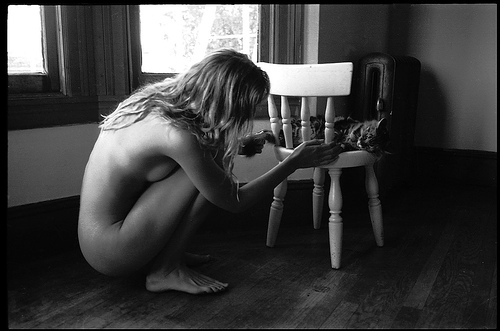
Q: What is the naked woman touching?
A: The chair.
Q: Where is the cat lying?
A: In chair.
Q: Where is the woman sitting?
A: Next to floor.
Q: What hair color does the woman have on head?
A: Blonde.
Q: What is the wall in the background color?
A: White.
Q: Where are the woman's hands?
A: On a small chair.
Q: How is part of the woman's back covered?
A: By her hair.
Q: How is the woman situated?
A: Squatting.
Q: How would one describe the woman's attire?
A: Naked.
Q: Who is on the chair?
A: Cat.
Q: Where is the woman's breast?
A: Touching her thigh.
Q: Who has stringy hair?
A: The blond woman.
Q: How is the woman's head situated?
A: Tilted to the right.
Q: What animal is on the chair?
A: A cat.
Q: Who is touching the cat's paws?
A: The young woman.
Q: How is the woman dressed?
A: Naked.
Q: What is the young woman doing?
A: Touching the cat's paws.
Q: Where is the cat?
A: On the chair.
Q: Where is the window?
A: Behind the woman.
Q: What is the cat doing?
A: Lying down.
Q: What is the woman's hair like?
A: Long and blonde.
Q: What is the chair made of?
A: Wood.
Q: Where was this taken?
A: In a living room.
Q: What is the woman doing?
A: Inspecting a chair.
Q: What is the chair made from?
A: Wood.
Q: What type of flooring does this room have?
A: Hardwood floors.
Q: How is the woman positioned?
A: She is crouched near the chair.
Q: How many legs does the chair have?
A: Four.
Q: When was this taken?
A: During the day.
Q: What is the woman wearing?
A: Nothing.